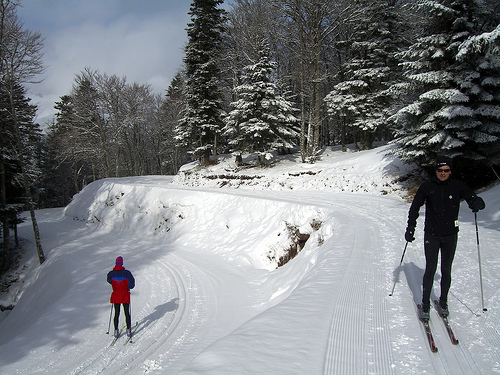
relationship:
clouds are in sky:
[2, 0, 239, 136] [2, 1, 331, 136]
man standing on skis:
[405, 155, 486, 322] [416, 294, 460, 352]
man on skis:
[405, 155, 486, 322] [416, 294, 460, 352]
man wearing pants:
[405, 155, 486, 322] [421, 231, 458, 308]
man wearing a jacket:
[405, 155, 486, 322] [403, 176, 482, 230]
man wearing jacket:
[405, 155, 486, 322] [403, 176, 482, 230]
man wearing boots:
[405, 155, 486, 322] [420, 296, 449, 323]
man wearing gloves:
[405, 155, 486, 322] [403, 196, 485, 242]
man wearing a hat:
[405, 155, 486, 322] [430, 155, 452, 173]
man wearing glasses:
[405, 155, 486, 322] [433, 165, 449, 175]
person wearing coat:
[107, 255, 136, 336] [104, 267, 135, 304]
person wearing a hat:
[107, 255, 136, 336] [113, 253, 125, 268]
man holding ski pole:
[405, 155, 486, 322] [469, 190, 489, 316]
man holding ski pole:
[405, 155, 486, 322] [385, 231, 413, 299]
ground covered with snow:
[2, 137, 498, 373] [1, 138, 498, 373]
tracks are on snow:
[30, 204, 497, 373] [1, 138, 498, 373]